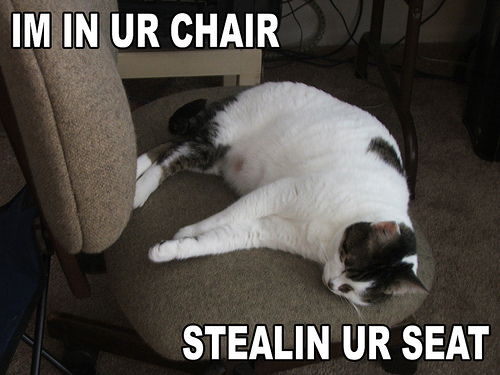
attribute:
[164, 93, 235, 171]
spots — black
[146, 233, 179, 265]
paw — white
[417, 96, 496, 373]
carpet — beige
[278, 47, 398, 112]
carpet — beige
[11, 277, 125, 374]
carpet — beige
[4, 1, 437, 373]
chair — grey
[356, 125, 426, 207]
spot — black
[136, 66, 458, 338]
cat — white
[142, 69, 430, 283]
cat — brown, white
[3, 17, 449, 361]
chair — gray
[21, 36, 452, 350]
chair — brown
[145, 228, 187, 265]
paws — back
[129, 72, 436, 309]
cat — white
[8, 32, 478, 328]
chair — brown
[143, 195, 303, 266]
front legs — white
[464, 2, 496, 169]
desktop — black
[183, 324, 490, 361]
words — white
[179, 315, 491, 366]
phrase — bad grammar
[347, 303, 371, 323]
whiskers — long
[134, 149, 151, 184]
leg — lower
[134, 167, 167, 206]
leg — lower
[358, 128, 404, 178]
spot — brown